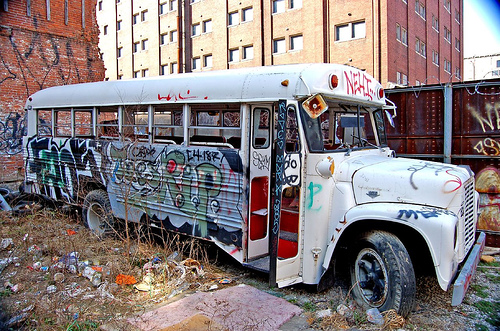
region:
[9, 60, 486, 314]
white and blue bus covered in graffiti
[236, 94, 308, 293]
red bus doors covered in garffiti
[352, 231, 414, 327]
old dusty tire on abandoned bus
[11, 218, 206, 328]
trash laying in brown grass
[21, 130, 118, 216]
thick black graffiti letters on back of bus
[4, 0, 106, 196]
red brick building behind bus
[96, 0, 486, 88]
square brick building with many windows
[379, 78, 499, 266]
wooden wall with yellow graffiti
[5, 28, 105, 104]
black graffiti paint on red brick building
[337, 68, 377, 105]
red letter graffiti on front of bus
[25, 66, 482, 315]
bus with graffiti on the side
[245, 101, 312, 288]
open doors on a bus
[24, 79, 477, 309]
white abandoned bus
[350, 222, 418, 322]
front right wheel of the bus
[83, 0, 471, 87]
red building in the background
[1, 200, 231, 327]
trash on the ground next to the bus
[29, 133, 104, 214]
black graffiti lettering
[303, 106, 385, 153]
front glass windows on the bus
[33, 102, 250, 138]
side passenger windows on the bus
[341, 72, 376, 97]
red graffiti lettering on the bus roof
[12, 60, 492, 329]
long white bus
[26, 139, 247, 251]
graffiti on side of bus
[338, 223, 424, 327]
front passenger tire on front of bus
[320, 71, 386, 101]
two red headlights on front of bus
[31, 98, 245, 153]
windows on side of white bus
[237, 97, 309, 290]
double bus door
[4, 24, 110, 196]
red brick wall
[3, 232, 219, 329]
trash on ground next to bus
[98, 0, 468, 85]
windows on side of brick building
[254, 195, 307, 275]
two red bus steps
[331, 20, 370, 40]
window on a brick building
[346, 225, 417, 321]
right front tire on the bus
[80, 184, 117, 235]
right back tire on the bus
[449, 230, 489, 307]
the bus' front bumper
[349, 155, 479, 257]
the bus hood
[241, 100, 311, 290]
the bus' doors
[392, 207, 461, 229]
black words on the right fender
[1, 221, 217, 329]
lots of trash on the ground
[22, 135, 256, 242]
painting on the side of the bus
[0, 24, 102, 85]
black letters on the side of the building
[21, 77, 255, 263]
graffiti on the bus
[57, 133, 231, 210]
graffiti on the bus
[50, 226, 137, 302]
trash on the ground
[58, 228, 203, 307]
trash on the ground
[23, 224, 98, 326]
trash on the ground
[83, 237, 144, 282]
trash on the ground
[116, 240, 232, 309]
trash on the ground